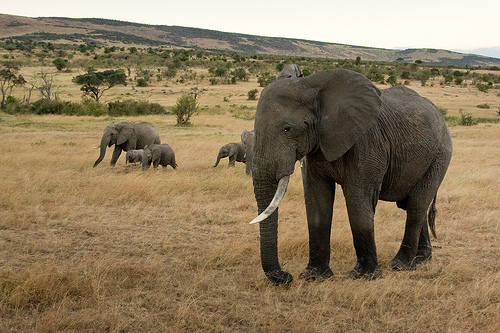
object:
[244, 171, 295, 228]
left tusk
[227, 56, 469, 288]
elephant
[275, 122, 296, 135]
left eye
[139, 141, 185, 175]
elephant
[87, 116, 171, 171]
adult elephant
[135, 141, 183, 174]
younger elephants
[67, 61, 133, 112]
trees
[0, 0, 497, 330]
savannah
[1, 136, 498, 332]
grass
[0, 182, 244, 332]
patch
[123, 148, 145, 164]
baby elephant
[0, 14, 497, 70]
hillside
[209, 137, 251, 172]
small elephants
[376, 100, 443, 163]
wrinkles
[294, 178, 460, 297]
four legs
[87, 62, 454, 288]
six elephants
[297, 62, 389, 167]
ears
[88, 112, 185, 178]
three elphants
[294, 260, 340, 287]
foot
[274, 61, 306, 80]
right ear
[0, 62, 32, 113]
tall tree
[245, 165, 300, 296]
trunk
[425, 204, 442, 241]
hair